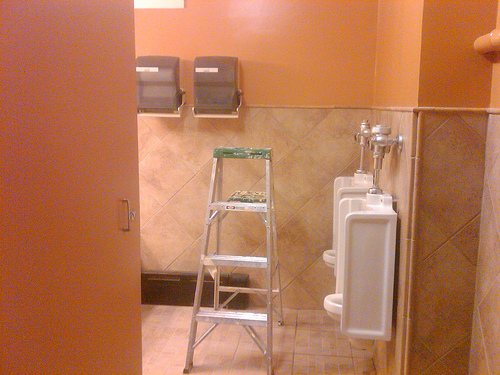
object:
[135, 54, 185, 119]
towel dispenser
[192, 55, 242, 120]
towel dispenser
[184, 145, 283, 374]
ladder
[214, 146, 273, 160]
top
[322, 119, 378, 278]
urinal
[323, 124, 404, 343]
urinal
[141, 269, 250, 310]
object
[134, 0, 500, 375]
wall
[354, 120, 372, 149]
flusher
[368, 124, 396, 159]
flusher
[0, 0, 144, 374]
door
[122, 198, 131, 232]
handle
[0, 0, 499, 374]
bathroom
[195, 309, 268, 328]
first rung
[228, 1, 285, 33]
light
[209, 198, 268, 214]
top rung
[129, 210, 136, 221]
lock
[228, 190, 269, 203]
paint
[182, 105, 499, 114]
border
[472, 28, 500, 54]
pipe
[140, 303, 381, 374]
floor